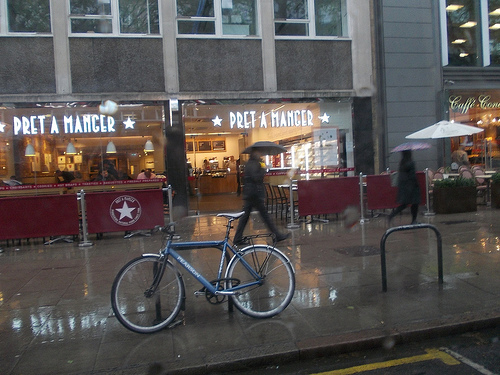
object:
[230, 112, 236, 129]
letter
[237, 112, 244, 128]
letter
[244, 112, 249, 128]
letter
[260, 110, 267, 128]
letter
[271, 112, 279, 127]
letter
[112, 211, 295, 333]
bicycle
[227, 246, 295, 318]
wheel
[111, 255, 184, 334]
wheel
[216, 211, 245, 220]
seat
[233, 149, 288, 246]
man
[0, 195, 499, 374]
sidewalk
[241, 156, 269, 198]
jacket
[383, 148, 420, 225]
woman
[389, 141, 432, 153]
umbrella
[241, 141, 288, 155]
umbrella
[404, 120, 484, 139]
umbrella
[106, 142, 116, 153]
lamp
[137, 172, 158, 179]
shirt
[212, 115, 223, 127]
star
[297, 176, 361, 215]
wall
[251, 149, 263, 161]
head